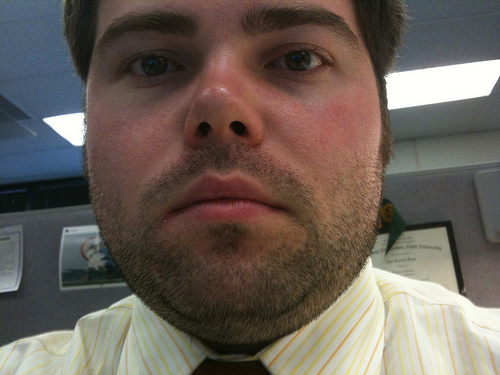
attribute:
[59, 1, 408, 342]
man — in cubicle, taking selfie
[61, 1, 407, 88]
hair — small dap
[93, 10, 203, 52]
eyebrow — arched, brown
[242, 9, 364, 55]
eyebrow — arched, brown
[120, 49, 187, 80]
eye — open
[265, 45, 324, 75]
eye — open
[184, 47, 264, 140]
nose — shiny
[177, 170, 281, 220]
lips — pink, red, light red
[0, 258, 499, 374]
shirt — white, yellow striped, white striped, orange striped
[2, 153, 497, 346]
wall — grey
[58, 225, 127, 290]
picture — in back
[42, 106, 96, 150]
light — on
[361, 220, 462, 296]
certificate — framed, black framed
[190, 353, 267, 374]
tie — brown, partial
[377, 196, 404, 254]
pennant — green, yellow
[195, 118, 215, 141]
nostril — dark